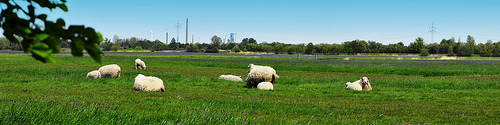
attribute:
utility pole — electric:
[181, 14, 190, 43]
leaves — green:
[6, 12, 56, 61]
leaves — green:
[350, 43, 352, 49]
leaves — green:
[446, 45, 454, 52]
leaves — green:
[169, 41, 175, 47]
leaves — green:
[153, 41, 162, 47]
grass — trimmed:
[386, 75, 484, 113]